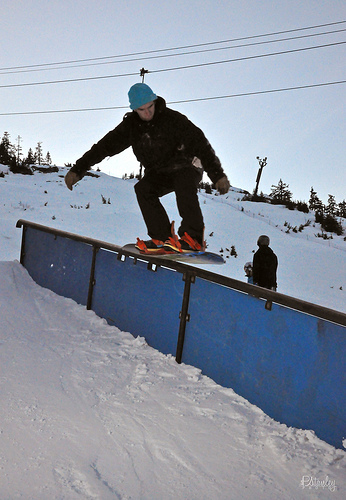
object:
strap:
[136, 237, 185, 253]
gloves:
[213, 179, 233, 190]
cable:
[29, 31, 293, 69]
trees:
[251, 155, 344, 239]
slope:
[234, 205, 288, 234]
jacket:
[70, 98, 225, 186]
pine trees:
[1, 127, 56, 174]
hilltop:
[0, 131, 345, 498]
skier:
[248, 232, 278, 294]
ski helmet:
[255, 233, 271, 247]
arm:
[174, 109, 228, 181]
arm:
[72, 113, 133, 179]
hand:
[212, 177, 232, 193]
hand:
[61, 162, 83, 190]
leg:
[128, 169, 175, 238]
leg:
[176, 173, 206, 241]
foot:
[133, 228, 177, 250]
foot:
[172, 230, 209, 253]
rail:
[17, 217, 344, 325]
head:
[129, 81, 157, 122]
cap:
[125, 81, 157, 109]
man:
[64, 80, 232, 251]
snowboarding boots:
[127, 227, 205, 257]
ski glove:
[63, 169, 85, 187]